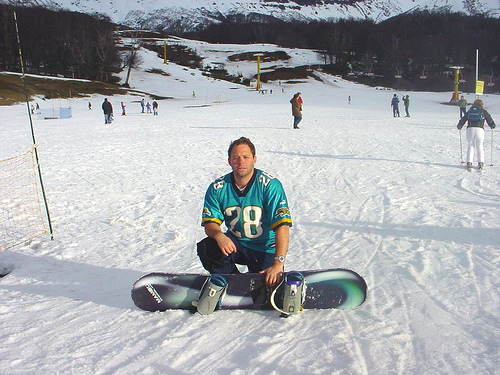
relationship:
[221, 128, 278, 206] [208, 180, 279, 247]
man wears jersey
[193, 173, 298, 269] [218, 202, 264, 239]
jersey number 28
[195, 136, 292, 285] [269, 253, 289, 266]
man wears watch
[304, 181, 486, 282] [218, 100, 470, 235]
tracks on snow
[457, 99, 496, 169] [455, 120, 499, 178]
lady on ski poles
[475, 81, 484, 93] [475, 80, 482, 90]
information has information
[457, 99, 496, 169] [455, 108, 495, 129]
lady wearing a coat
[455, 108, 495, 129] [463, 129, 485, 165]
coat and pants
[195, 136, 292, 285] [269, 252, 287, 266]
man wearing a watch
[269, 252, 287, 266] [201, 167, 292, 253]
watch and jersey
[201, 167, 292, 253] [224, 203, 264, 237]
jersey with number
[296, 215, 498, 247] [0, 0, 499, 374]
shadow being cast on snow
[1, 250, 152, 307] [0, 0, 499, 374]
shadow being cast on snow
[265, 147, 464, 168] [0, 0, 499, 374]
shadow being cast on snow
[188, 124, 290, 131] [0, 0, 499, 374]
shadow being cast on snow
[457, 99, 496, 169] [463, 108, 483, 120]
lady wearing a backpack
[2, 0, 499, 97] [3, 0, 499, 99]
hills covered with snow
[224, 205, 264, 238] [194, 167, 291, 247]
28 print on a jersey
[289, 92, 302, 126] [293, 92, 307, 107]
person holding child